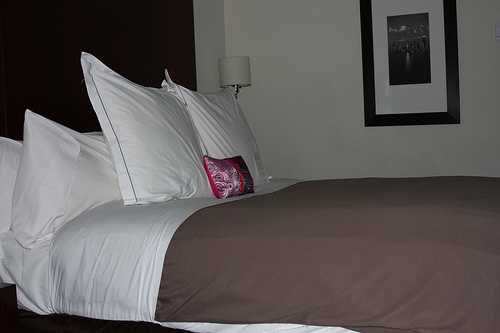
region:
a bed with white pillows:
[8, 40, 470, 318]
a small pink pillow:
[189, 111, 272, 234]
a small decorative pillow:
[179, 124, 295, 217]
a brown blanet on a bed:
[88, 65, 472, 322]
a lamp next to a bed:
[211, 37, 327, 197]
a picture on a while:
[326, 3, 467, 166]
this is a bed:
[41, 51, 485, 329]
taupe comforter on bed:
[154, 154, 498, 328]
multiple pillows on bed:
[14, 32, 258, 262]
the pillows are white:
[34, 25, 262, 255]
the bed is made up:
[14, 55, 497, 331]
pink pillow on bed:
[194, 126, 266, 201]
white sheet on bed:
[34, 183, 220, 327]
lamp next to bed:
[205, 30, 275, 133]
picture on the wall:
[339, 0, 476, 143]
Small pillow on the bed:
[194, 150, 264, 207]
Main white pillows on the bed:
[14, 45, 300, 253]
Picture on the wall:
[352, 5, 469, 146]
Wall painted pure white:
[256, 13, 363, 173]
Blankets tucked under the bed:
[10, 197, 497, 330]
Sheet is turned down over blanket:
[14, 115, 336, 331]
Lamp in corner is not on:
[205, 31, 260, 105]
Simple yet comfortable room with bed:
[3, 6, 493, 327]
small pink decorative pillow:
[204, 149, 256, 198]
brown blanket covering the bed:
[155, 169, 497, 331]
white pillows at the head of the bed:
[5, 65, 266, 233]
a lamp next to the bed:
[215, 51, 252, 101]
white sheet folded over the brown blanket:
[48, 166, 302, 321]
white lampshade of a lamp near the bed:
[213, 53, 253, 87]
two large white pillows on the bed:
[81, 47, 269, 203]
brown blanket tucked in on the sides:
[155, 179, 497, 329]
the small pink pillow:
[202, 152, 255, 200]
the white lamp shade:
[218, 55, 250, 88]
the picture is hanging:
[358, 0, 460, 127]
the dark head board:
[1, 0, 198, 140]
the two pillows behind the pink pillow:
[78, 47, 270, 204]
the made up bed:
[0, 49, 499, 331]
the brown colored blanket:
[154, 175, 499, 329]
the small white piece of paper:
[250, 149, 270, 185]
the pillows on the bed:
[0, 50, 499, 331]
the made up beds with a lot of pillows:
[0, 50, 499, 332]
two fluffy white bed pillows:
[81, 48, 277, 214]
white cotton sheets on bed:
[13, 134, 298, 317]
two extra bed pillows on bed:
[3, 112, 98, 240]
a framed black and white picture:
[352, 0, 473, 139]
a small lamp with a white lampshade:
[209, 40, 260, 110]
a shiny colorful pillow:
[197, 140, 270, 214]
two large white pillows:
[66, 33, 281, 201]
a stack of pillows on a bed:
[0, 46, 299, 253]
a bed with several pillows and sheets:
[4, 31, 499, 317]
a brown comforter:
[153, 143, 498, 325]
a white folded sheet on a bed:
[0, 175, 311, 331]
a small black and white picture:
[382, 9, 439, 89]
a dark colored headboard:
[2, 2, 214, 163]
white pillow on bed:
[78, 52, 220, 204]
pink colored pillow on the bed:
[191, 150, 250, 195]